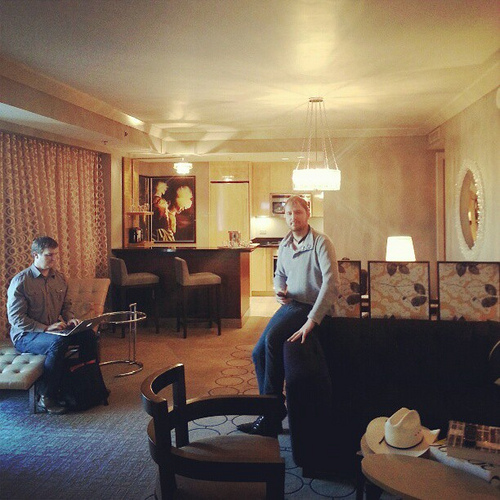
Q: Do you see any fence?
A: No, there are no fences.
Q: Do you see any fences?
A: No, there are no fences.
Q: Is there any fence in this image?
A: No, there are no fences.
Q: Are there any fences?
A: No, there are no fences.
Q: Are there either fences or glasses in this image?
A: No, there are no fences or glasses.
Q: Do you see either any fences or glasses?
A: No, there are no fences or glasses.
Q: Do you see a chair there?
A: Yes, there is a chair.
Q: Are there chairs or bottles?
A: Yes, there is a chair.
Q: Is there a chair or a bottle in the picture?
A: Yes, there is a chair.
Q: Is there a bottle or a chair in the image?
A: Yes, there is a chair.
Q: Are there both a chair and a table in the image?
A: Yes, there are both a chair and a table.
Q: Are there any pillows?
A: No, there are no pillows.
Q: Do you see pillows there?
A: No, there are no pillows.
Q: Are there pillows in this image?
A: No, there are no pillows.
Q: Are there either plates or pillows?
A: No, there are no pillows or plates.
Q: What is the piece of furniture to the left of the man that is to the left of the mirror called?
A: The piece of furniture is a chair.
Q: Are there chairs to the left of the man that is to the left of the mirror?
A: Yes, there is a chair to the left of the man.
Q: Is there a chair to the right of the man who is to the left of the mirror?
A: No, the chair is to the left of the man.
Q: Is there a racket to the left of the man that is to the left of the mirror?
A: No, there is a chair to the left of the man.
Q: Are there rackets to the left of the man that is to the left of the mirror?
A: No, there is a chair to the left of the man.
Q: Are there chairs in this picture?
A: Yes, there is a chair.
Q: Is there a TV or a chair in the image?
A: Yes, there is a chair.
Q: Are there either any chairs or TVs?
A: Yes, there is a chair.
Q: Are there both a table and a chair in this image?
A: Yes, there are both a chair and a table.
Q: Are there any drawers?
A: No, there are no drawers.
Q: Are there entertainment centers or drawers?
A: No, there are no drawers or entertainment centers.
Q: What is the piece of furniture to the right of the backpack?
A: The piece of furniture is a chair.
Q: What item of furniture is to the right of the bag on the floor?
A: The piece of furniture is a chair.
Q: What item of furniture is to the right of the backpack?
A: The piece of furniture is a chair.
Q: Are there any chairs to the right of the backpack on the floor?
A: Yes, there is a chair to the right of the backpack.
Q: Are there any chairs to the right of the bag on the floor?
A: Yes, there is a chair to the right of the backpack.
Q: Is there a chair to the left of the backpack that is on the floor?
A: No, the chair is to the right of the backpack.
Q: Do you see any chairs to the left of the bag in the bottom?
A: No, the chair is to the right of the backpack.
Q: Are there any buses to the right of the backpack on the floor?
A: No, there is a chair to the right of the backpack.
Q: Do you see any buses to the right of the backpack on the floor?
A: No, there is a chair to the right of the backpack.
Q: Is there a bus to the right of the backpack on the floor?
A: No, there is a chair to the right of the backpack.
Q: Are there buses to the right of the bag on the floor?
A: No, there is a chair to the right of the backpack.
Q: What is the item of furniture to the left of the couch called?
A: The piece of furniture is a chair.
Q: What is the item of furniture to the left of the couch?
A: The piece of furniture is a chair.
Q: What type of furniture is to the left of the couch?
A: The piece of furniture is a chair.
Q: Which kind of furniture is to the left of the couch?
A: The piece of furniture is a chair.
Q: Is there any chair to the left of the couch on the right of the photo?
A: Yes, there is a chair to the left of the couch.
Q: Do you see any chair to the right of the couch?
A: No, the chair is to the left of the couch.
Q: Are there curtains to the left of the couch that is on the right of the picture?
A: No, there is a chair to the left of the couch.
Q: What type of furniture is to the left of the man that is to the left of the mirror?
A: The piece of furniture is a chair.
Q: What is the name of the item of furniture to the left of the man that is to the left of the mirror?
A: The piece of furniture is a chair.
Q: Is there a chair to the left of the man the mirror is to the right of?
A: Yes, there is a chair to the left of the man.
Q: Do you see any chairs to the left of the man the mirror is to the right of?
A: Yes, there is a chair to the left of the man.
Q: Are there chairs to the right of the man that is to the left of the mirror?
A: No, the chair is to the left of the man.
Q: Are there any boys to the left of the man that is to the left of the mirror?
A: No, there is a chair to the left of the man.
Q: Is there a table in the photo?
A: Yes, there is a table.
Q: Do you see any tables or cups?
A: Yes, there is a table.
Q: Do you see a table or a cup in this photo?
A: Yes, there is a table.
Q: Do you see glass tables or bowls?
A: Yes, there is a glass table.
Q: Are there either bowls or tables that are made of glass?
A: Yes, the table is made of glass.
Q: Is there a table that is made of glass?
A: Yes, there is a table that is made of glass.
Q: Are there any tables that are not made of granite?
A: Yes, there is a table that is made of glass.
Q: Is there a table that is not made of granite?
A: Yes, there is a table that is made of glass.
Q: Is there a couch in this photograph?
A: Yes, there is a couch.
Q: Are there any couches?
A: Yes, there is a couch.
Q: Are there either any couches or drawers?
A: Yes, there is a couch.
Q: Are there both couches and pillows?
A: No, there is a couch but no pillows.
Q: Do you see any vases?
A: No, there are no vases.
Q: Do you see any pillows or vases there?
A: No, there are no vases or pillows.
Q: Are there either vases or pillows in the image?
A: No, there are no vases or pillows.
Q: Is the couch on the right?
A: Yes, the couch is on the right of the image.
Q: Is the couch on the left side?
A: No, the couch is on the right of the image.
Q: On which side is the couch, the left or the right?
A: The couch is on the right of the image.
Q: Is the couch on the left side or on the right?
A: The couch is on the right of the image.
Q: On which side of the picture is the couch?
A: The couch is on the right of the image.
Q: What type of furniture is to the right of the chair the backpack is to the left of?
A: The piece of furniture is a couch.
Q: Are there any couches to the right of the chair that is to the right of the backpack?
A: Yes, there is a couch to the right of the chair.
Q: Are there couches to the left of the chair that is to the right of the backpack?
A: No, the couch is to the right of the chair.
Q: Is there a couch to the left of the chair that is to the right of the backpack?
A: No, the couch is to the right of the chair.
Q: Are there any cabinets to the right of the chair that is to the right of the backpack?
A: No, there is a couch to the right of the chair.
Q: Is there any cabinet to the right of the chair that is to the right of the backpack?
A: No, there is a couch to the right of the chair.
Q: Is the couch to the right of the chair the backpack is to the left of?
A: Yes, the couch is to the right of the chair.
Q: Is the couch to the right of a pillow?
A: No, the couch is to the right of the chair.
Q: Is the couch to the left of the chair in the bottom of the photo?
A: No, the couch is to the right of the chair.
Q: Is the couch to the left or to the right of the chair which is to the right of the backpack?
A: The couch is to the right of the chair.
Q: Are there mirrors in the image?
A: Yes, there is a mirror.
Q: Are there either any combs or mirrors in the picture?
A: Yes, there is a mirror.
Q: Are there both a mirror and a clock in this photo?
A: No, there is a mirror but no clocks.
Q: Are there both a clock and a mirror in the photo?
A: No, there is a mirror but no clocks.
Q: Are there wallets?
A: No, there are no wallets.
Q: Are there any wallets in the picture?
A: No, there are no wallets.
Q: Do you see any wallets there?
A: No, there are no wallets.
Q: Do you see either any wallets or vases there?
A: No, there are no wallets or vases.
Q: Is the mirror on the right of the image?
A: Yes, the mirror is on the right of the image.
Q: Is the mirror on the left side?
A: No, the mirror is on the right of the image.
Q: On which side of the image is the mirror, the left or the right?
A: The mirror is on the right of the image.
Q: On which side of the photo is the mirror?
A: The mirror is on the right of the image.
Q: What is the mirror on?
A: The mirror is on the wall.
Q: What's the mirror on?
A: The mirror is on the wall.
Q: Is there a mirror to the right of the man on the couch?
A: Yes, there is a mirror to the right of the man.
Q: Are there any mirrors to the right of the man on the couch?
A: Yes, there is a mirror to the right of the man.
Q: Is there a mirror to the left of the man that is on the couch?
A: No, the mirror is to the right of the man.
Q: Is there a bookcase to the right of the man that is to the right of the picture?
A: No, there is a mirror to the right of the man.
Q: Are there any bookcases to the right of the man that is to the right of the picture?
A: No, there is a mirror to the right of the man.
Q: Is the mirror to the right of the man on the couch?
A: Yes, the mirror is to the right of the man.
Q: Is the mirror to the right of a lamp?
A: No, the mirror is to the right of the man.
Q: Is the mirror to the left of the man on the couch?
A: No, the mirror is to the right of the man.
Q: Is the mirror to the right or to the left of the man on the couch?
A: The mirror is to the right of the man.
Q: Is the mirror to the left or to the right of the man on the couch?
A: The mirror is to the right of the man.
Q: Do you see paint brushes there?
A: No, there are no paint brushes.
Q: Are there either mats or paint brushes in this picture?
A: No, there are no paint brushes or mats.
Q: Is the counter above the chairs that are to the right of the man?
A: Yes, the counter is above the chairs.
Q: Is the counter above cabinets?
A: No, the counter is above the chairs.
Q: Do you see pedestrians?
A: No, there are no pedestrians.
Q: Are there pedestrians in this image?
A: No, there are no pedestrians.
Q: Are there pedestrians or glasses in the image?
A: No, there are no pedestrians or glasses.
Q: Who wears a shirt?
A: The man wears a shirt.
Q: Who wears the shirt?
A: The man wears a shirt.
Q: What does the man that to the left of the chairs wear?
A: The man wears a shirt.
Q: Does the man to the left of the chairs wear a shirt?
A: Yes, the man wears a shirt.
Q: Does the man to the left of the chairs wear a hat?
A: No, the man wears a shirt.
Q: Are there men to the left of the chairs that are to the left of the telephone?
A: Yes, there is a man to the left of the chairs.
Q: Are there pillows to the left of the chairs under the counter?
A: No, there is a man to the left of the chairs.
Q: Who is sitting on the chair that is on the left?
A: The man is sitting on the chair.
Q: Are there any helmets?
A: No, there are no helmets.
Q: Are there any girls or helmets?
A: No, there are no helmets or girls.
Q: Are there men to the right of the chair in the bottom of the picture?
A: Yes, there is a man to the right of the chair.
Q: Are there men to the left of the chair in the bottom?
A: No, the man is to the right of the chair.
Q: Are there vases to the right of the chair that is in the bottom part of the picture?
A: No, there is a man to the right of the chair.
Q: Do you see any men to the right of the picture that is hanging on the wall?
A: Yes, there is a man to the right of the picture.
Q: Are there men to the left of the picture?
A: No, the man is to the right of the picture.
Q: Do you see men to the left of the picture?
A: No, the man is to the right of the picture.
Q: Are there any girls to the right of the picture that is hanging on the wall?
A: No, there is a man to the right of the picture.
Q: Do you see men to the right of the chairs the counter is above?
A: Yes, there is a man to the right of the chairs.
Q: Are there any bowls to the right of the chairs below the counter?
A: No, there is a man to the right of the chairs.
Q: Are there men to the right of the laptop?
A: Yes, there is a man to the right of the laptop.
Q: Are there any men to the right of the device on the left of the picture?
A: Yes, there is a man to the right of the laptop.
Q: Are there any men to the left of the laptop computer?
A: No, the man is to the right of the laptop computer.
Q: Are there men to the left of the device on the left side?
A: No, the man is to the right of the laptop computer.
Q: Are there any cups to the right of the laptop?
A: No, there is a man to the right of the laptop.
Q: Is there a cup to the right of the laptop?
A: No, there is a man to the right of the laptop.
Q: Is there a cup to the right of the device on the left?
A: No, there is a man to the right of the laptop.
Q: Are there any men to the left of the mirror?
A: Yes, there is a man to the left of the mirror.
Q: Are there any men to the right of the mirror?
A: No, the man is to the left of the mirror.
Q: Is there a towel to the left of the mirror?
A: No, there is a man to the left of the mirror.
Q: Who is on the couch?
A: The man is on the couch.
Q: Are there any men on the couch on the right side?
A: Yes, there is a man on the couch.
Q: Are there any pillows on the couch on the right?
A: No, there is a man on the couch.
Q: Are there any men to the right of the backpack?
A: Yes, there is a man to the right of the backpack.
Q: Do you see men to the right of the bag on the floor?
A: Yes, there is a man to the right of the backpack.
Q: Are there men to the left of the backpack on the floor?
A: No, the man is to the right of the backpack.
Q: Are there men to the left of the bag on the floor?
A: No, the man is to the right of the backpack.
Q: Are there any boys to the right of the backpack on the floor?
A: No, there is a man to the right of the backpack.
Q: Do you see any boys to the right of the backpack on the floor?
A: No, there is a man to the right of the backpack.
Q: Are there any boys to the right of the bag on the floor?
A: No, there is a man to the right of the backpack.